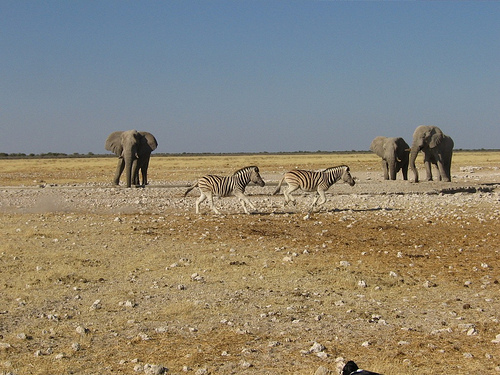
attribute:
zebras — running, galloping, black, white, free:
[179, 155, 354, 215]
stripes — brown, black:
[209, 167, 337, 202]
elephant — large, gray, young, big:
[104, 126, 153, 189]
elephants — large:
[374, 124, 448, 183]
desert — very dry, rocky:
[3, 152, 499, 373]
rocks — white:
[76, 175, 499, 351]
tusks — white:
[117, 149, 139, 161]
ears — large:
[105, 130, 157, 159]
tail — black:
[179, 185, 193, 205]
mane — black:
[234, 163, 254, 172]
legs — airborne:
[274, 191, 299, 206]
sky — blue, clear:
[2, 3, 499, 152]